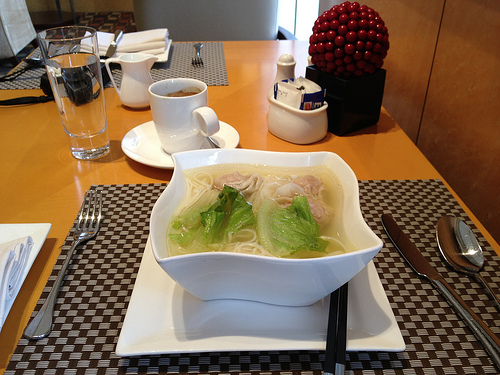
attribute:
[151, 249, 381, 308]
bowl — designed, full, wavy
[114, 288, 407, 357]
plate — square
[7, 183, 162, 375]
placemat — chekered, woven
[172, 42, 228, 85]
placemat — chekered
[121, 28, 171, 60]
napkin — stacked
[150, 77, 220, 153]
cup — white, dirty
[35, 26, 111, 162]
glass — full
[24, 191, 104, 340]
fork — siver, silver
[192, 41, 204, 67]
fork — metal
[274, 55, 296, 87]
salt shaker — white